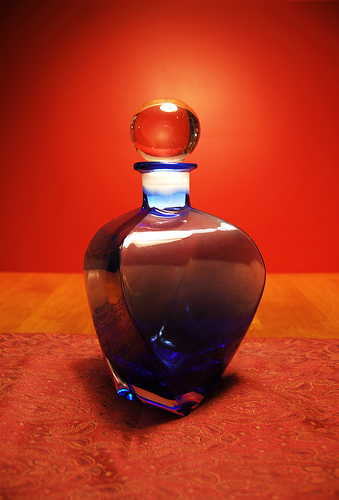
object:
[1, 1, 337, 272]
wall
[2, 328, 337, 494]
cloth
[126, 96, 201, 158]
glass top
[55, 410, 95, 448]
print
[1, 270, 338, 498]
table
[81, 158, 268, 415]
carafe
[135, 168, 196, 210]
bottle neck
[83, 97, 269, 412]
vase